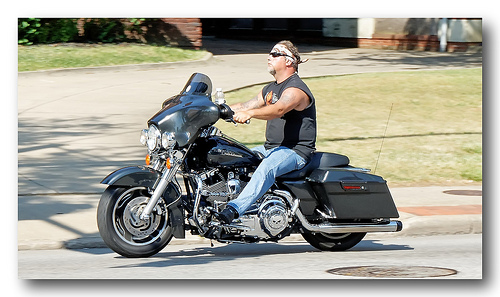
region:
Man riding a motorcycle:
[88, 36, 412, 259]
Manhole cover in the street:
[321, 261, 463, 283]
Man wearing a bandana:
[262, 36, 314, 80]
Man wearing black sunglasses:
[263, 36, 313, 81]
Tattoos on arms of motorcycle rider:
[222, 82, 317, 127]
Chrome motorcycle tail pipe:
[286, 203, 411, 240]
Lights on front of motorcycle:
[134, 121, 185, 174]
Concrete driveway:
[51, 73, 151, 109]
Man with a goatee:
[263, 61, 280, 78]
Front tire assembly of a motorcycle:
[93, 159, 189, 263]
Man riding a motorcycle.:
[91, 39, 408, 259]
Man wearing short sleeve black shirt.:
[258, 76, 327, 156]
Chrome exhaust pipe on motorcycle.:
[308, 215, 407, 235]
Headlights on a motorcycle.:
[134, 126, 176, 152]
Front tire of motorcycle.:
[93, 181, 183, 261]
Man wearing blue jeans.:
[230, 145, 303, 215]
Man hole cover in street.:
[319, 258, 472, 282]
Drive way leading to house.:
[23, 70, 128, 182]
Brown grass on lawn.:
[362, 77, 474, 160]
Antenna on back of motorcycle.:
[370, 91, 405, 179]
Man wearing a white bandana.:
[218, 38, 317, 224]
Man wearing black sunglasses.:
[216, 39, 317, 223]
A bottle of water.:
[213, 86, 224, 105]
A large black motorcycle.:
[96, 73, 402, 256]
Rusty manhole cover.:
[326, 263, 457, 278]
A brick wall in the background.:
[74, 16, 201, 51]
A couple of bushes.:
[18, 18, 194, 50]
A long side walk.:
[18, 183, 483, 252]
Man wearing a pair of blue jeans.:
[215, 40, 317, 225]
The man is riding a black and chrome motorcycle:
[95, 40, 410, 260]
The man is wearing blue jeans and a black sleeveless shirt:
[222, 70, 318, 223]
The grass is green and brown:
[22, 42, 473, 179]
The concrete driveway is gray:
[16, 50, 471, 196]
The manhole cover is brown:
[329, 258, 459, 279]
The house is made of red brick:
[93, 22, 478, 67]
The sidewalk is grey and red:
[382, 183, 489, 228]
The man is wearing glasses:
[266, 46, 298, 64]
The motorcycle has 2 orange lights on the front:
[140, 154, 173, 169]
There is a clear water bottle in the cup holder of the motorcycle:
[214, 88, 228, 107]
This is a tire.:
[75, 157, 203, 264]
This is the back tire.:
[282, 183, 389, 255]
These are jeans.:
[194, 125, 325, 232]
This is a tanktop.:
[247, 74, 360, 198]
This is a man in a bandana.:
[260, 42, 324, 74]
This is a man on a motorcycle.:
[63, 38, 420, 254]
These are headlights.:
[121, 116, 185, 173]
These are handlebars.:
[173, 76, 263, 126]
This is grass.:
[341, 70, 436, 105]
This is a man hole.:
[317, 253, 471, 276]